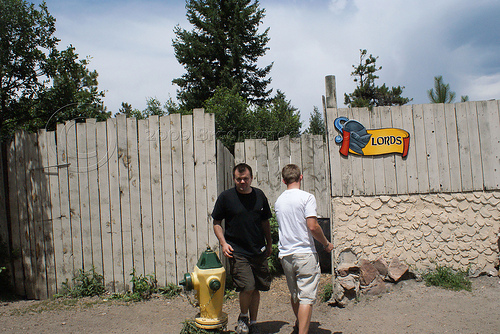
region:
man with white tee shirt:
[270, 153, 340, 330]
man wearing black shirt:
[210, 156, 280, 328]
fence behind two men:
[10, 68, 496, 314]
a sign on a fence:
[330, 107, 415, 164]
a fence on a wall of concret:
[315, 70, 490, 280]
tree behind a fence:
[119, 1, 351, 159]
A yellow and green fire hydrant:
[185, 240, 232, 330]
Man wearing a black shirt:
[205, 155, 276, 260]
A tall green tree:
[166, 0, 277, 115]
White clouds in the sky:
[21, 0, 496, 115]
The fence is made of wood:
[0, 71, 495, 296]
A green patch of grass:
[416, 260, 477, 296]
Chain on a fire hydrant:
[175, 280, 205, 310]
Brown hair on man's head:
[225, 157, 255, 192]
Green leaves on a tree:
[198, 85, 301, 151]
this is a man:
[263, 145, 343, 325]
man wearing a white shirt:
[274, 185, 337, 265]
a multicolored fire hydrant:
[159, 222, 245, 332]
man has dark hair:
[228, 161, 260, 183]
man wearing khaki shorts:
[279, 240, 334, 310]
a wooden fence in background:
[14, 77, 317, 299]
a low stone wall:
[328, 183, 497, 291]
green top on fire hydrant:
[184, 235, 231, 280]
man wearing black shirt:
[197, 153, 273, 332]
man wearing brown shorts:
[207, 146, 282, 322]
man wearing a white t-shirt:
[264, 156, 343, 319]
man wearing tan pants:
[261, 157, 341, 327]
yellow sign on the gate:
[326, 107, 411, 167]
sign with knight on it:
[327, 104, 416, 165]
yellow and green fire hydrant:
[172, 242, 239, 325]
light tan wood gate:
[14, 108, 228, 282]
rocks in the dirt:
[332, 246, 417, 299]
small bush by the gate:
[55, 265, 107, 297]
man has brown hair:
[208, 146, 245, 174]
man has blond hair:
[273, 166, 310, 174]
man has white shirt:
[269, 157, 319, 268]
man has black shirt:
[209, 184, 315, 265]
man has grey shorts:
[273, 244, 331, 286]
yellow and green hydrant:
[179, 242, 215, 327]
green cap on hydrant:
[196, 248, 215, 268]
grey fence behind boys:
[58, 116, 186, 292]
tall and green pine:
[186, 1, 295, 144]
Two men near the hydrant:
[214, 151, 334, 324]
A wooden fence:
[85, 139, 178, 243]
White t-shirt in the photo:
[275, 195, 313, 262]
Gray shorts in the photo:
[280, 249, 320, 300]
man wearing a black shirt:
[194, 179, 276, 251]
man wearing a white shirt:
[266, 183, 336, 255]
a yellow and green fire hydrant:
[169, 247, 246, 332]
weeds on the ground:
[27, 252, 197, 314]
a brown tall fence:
[23, 72, 484, 282]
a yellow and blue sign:
[326, 107, 415, 163]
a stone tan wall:
[332, 182, 497, 288]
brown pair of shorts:
[214, 237, 277, 304]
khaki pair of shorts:
[270, 249, 330, 304]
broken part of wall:
[330, 236, 410, 296]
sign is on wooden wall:
[333, 113, 410, 158]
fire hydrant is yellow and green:
[179, 245, 227, 331]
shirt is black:
[211, 187, 272, 249]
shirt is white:
[272, 190, 316, 257]